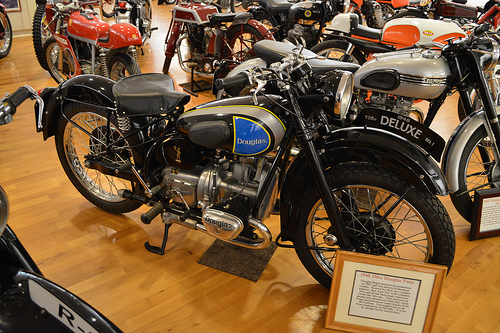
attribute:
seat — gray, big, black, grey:
[98, 70, 190, 112]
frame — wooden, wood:
[322, 229, 453, 330]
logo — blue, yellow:
[236, 110, 280, 166]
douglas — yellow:
[238, 134, 270, 145]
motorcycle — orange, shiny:
[42, 17, 150, 53]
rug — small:
[205, 237, 287, 275]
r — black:
[50, 299, 89, 327]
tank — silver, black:
[157, 165, 213, 210]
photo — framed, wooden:
[309, 240, 469, 332]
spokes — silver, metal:
[86, 132, 122, 171]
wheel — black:
[64, 99, 147, 225]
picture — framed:
[336, 242, 450, 329]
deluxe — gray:
[379, 109, 428, 138]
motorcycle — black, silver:
[243, 32, 498, 159]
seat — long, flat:
[258, 24, 351, 74]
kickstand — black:
[144, 218, 182, 263]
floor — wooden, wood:
[29, 228, 279, 331]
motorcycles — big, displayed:
[51, 24, 465, 203]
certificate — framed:
[477, 182, 498, 230]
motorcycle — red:
[151, 9, 271, 78]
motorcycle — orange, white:
[326, 14, 481, 63]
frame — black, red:
[470, 193, 497, 236]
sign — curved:
[358, 105, 441, 152]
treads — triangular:
[337, 164, 390, 185]